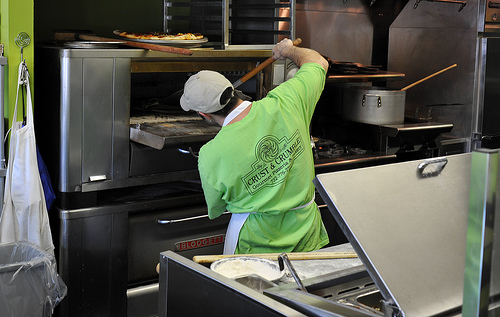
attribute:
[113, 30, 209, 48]
pan — metal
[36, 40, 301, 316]
oven — metal, open, dark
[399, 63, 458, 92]
spoon — wooden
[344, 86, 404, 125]
pot — metal, large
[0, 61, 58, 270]
apron — white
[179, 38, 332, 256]
man — making pizza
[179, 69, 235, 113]
baseball cap — white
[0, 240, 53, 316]
trash can — gray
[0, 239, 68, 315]
liner — plastic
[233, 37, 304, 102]
paddle — wooden, wood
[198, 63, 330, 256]
shirt — green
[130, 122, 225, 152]
door — open, metal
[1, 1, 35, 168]
wall — green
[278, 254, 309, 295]
ladle — metal, curved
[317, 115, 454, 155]
shelf — metal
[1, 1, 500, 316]
kitchen — commercial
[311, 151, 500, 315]
lid — metal, open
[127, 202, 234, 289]
door — closed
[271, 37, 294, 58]
glove — plastic